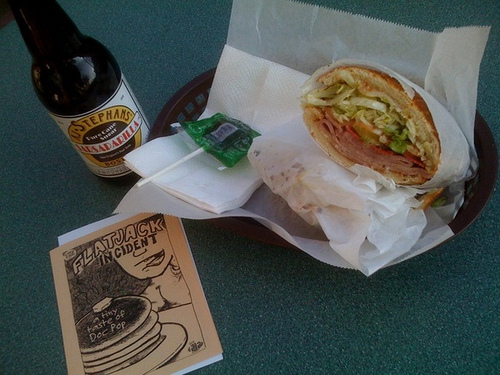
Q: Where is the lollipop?
A: On the napkin.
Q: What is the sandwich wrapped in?
A: Wax paper.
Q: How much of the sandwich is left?
A: Half.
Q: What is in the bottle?
A: Sasparilla.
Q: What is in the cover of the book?
A: Pancakes.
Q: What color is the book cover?
A: Brown and black.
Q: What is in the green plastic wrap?
A: Lollipop.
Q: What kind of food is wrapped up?
A: Sandwich.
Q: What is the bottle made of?
A: Glass.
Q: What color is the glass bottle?
A: Brown.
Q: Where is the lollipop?
A: On the napkins.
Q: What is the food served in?
A: Plastic basket.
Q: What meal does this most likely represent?
A: Lunch.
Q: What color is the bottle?
A: Brown.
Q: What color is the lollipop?
A: Green.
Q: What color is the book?
A: Light brown.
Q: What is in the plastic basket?
A: A sandwich.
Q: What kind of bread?
A: White.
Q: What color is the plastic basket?
A: Brown.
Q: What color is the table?
A: Dark green.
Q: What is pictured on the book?
A: Pancakes.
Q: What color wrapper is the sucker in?
A: Green.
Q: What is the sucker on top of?
A: Napkins.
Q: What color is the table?
A: Green.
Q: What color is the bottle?
A: Brown.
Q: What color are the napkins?
A: 2.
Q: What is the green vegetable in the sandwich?
A: Lettuce.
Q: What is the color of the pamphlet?
A: Brown.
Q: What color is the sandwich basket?
A: Brown.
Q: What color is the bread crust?
A: Brown.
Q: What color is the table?
A: Green.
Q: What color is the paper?
A: White.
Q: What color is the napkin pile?
A: White.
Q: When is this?
A: Lunchtime.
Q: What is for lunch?
A: A sandwich.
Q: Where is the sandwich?
A: In a basket.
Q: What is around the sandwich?
A: Paper.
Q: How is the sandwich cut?
A: In half.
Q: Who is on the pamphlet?
A: A child.